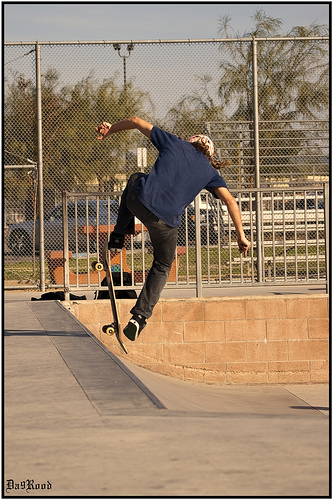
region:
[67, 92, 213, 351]
person with long hair on skateboard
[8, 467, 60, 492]
black writing on photo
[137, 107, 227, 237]
person in blue shirt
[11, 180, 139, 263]
grey vehicle in background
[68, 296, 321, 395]
stone wall on skate ramp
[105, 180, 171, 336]
man in black jeans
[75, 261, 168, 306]
black bag on ground in photo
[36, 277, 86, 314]
black shirt on ground in photo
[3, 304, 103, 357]
shadow on ground in photo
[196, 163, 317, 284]
bleachers in background of photo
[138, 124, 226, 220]
The dark blue t-shirt the man is wearing.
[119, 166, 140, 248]
The left pant leg of the man.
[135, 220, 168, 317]
The right pant leg of the man.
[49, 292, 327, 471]
The ramp the man is jumping.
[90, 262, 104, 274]
The front wheels of the skateboard.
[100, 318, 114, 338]
The back wheels of the skateboard.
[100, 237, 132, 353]
The skateboard the guy is using.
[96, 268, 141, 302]
The black back pack behind the wrought iron fence.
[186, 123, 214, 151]
The helmet on the rider's head.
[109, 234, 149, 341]
The black sneakers the skater is wearing.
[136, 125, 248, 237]
man wears blue shirt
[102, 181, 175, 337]
man wears black jeans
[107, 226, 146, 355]
man wears black shoes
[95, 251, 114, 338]
skateboard has tan wheels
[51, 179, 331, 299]
fence is metallic and grey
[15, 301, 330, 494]
sidewalk is dark grey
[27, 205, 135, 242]
silver car behind fence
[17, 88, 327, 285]
tall chain link fence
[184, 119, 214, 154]
man wears white helmet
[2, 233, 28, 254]
car has black tires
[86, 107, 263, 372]
Skateboarder doing a trick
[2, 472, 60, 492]
The photographer's signature stamp.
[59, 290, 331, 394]
The wall is made of concrete blocks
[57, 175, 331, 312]
Fence made of metal.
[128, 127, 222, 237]
The skateboarder's shirt is blue.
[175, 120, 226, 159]
Helmet on the skateboarder's head.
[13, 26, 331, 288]
Chain link fence surrounding the skate park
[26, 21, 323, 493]
Photo taken at a skate park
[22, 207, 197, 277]
Picnic table behind the fence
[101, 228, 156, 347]
Black sneakers on the skateboarder.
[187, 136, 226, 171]
Hair sticking out behind helmet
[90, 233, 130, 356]
Skateboard in the air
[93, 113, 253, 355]
Person performing skateboard trick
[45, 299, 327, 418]
Concrete skateboarding ramp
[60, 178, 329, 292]
Metal fence along edge of ramp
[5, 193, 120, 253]
Silver car parked in street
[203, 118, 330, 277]
Metal bleachers for audience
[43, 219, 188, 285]
Empty, brown picnic table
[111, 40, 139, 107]
Light post with two lights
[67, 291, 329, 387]
Concrete bricks line wall